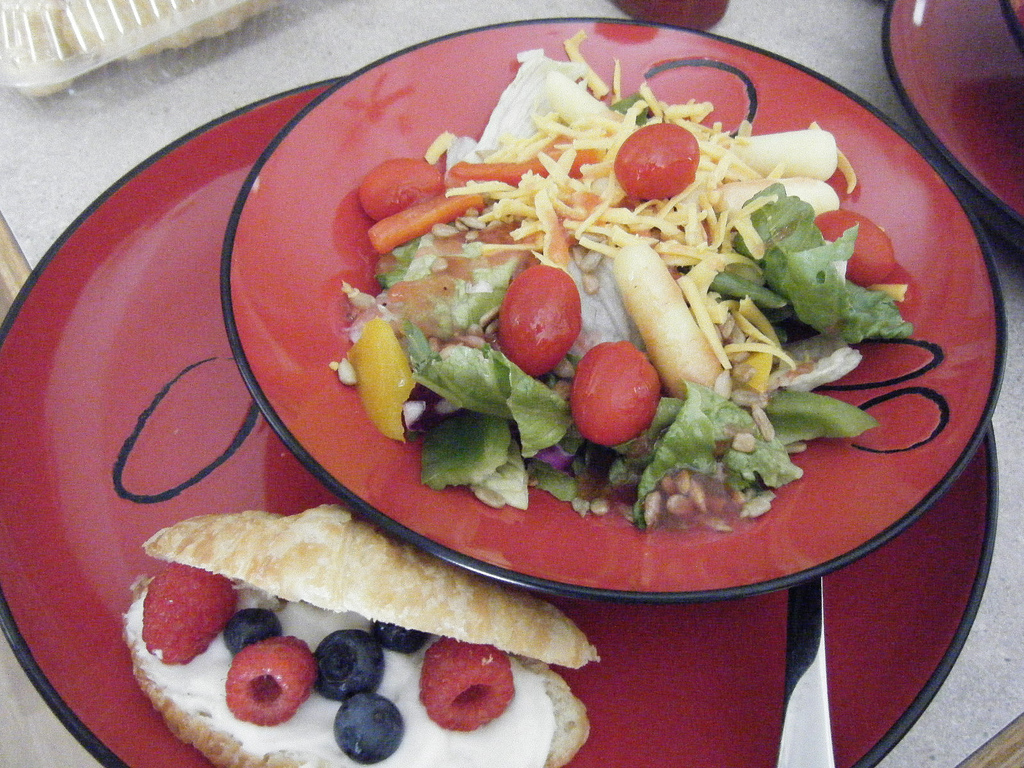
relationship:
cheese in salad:
[615, 210, 756, 288] [331, 35, 900, 509]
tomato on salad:
[812, 198, 897, 286] [437, 268, 647, 508]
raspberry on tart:
[409, 647, 518, 738] [102, 510, 545, 765]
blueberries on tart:
[286, 595, 425, 758] [63, 508, 575, 764]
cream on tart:
[420, 716, 492, 764] [107, 506, 609, 762]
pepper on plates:
[340, 320, 429, 459] [13, 33, 1002, 763]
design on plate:
[55, 312, 284, 531] [27, 111, 980, 747]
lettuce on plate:
[374, 329, 582, 505] [199, 20, 992, 606]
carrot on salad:
[355, 167, 515, 263] [366, 55, 900, 490]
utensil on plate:
[744, 601, 874, 762] [27, 156, 1019, 762]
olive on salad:
[567, 327, 665, 461] [366, 44, 835, 483]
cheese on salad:
[500, 148, 615, 224] [340, 68, 917, 553]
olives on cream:
[318, 638, 409, 762] [403, 675, 540, 758]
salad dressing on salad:
[634, 476, 775, 546] [331, 35, 900, 509]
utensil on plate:
[754, 601, 828, 755] [27, 111, 980, 747]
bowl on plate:
[253, 40, 973, 607] [52, 46, 886, 764]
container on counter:
[5, 1, 292, 105] [13, 5, 1020, 746]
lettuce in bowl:
[457, 48, 594, 174] [184, 33, 967, 585]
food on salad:
[335, 262, 439, 464] [340, 68, 917, 553]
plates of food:
[13, 33, 966, 764] [407, 57, 870, 587]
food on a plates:
[325, 94, 937, 501] [13, 33, 1002, 763]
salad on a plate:
[392, 61, 855, 479] [199, 20, 992, 606]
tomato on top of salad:
[610, 106, 697, 208] [331, 35, 900, 509]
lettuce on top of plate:
[398, 318, 524, 513] [212, 11, 932, 619]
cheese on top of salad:
[521, 147, 608, 208] [340, 89, 876, 541]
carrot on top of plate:
[373, 181, 490, 244] [199, 20, 992, 606]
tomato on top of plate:
[491, 245, 585, 397] [199, 20, 992, 606]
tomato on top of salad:
[560, 340, 671, 440] [340, 68, 917, 553]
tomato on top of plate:
[605, 106, 711, 202] [199, 20, 992, 606]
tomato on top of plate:
[812, 198, 897, 286] [199, 20, 992, 606]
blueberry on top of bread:
[348, 681, 401, 764] [94, 493, 624, 764]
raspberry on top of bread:
[145, 553, 225, 675] [100, 459, 615, 749]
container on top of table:
[5, 1, 291, 105] [24, 1, 1021, 755]